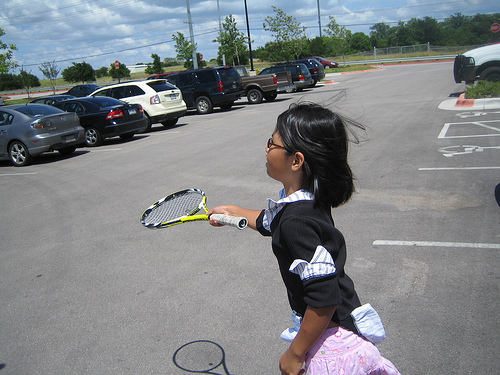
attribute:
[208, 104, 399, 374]
girl — asian, light skinned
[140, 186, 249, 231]
racket — white,black,yellow, black, yellow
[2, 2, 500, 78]
sky — cloudy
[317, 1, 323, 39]
pole — gray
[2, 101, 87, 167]
car — parked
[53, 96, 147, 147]
car — black, parked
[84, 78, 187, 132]
car — white, parked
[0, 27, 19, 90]
tree — green, leafy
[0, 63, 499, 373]
parking lot — paved, semi full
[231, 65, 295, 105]
truck — parked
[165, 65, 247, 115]
suv — parked, dark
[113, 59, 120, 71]
sign — red, white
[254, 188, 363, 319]
shirt — black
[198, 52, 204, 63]
sign — red, white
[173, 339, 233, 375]
shadow — racket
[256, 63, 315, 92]
mini van — parked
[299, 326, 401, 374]
skirt — pink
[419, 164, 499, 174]
line — white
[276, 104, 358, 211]
hair — dark, straight, shiny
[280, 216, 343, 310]
sleeve — turned up